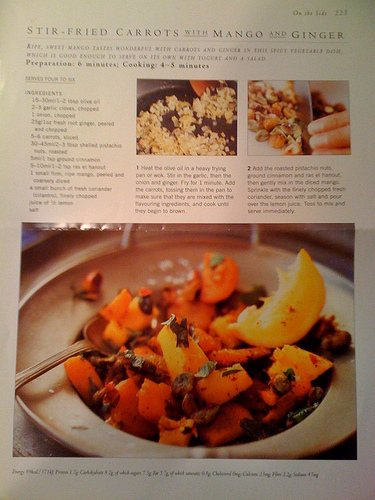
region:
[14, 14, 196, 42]
This is a stir-fried carrots recipie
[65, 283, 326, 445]
This is a picture of food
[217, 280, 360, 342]
This is a lemon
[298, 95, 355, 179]
This is a hand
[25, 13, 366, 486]
This is a recipe page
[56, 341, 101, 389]
This is a spoon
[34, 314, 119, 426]
The spoon is silver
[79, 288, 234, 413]
The carrots are orange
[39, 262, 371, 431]
This is a bowl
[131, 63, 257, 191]
This is a picture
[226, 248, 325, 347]
a lemon wedge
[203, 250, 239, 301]
slice of tomato with herb flakes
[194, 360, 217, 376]
an undetermined herb flake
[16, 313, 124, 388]
partial silver spoon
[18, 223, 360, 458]
silver serving platter with sauteed food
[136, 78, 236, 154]
thumbnail image of sauteed onions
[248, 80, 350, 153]
thumbnail image of chopping instructions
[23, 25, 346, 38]
recipe title for article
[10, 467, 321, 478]
a caption describing the recipe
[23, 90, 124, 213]
list of ingredients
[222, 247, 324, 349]
peice of food on a plate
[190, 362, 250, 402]
peice of food on a plate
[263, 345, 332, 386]
peice of food on a plate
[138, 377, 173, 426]
peice of food on a plate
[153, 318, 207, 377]
peice of food on a plate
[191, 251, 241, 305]
peice of food on a plate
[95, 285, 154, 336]
peice of food on a plate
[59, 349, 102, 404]
peice of food on a plate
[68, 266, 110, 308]
peice of food on a plate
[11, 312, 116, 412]
silver spoon on a plate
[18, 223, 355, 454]
a plate of food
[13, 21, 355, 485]
A recipe on a page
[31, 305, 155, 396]
a spoon in a bowl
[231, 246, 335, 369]
a lemon slice on a plate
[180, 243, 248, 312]
tomato slices on a plate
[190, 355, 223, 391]
green sage on food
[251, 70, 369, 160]
a hand chopping food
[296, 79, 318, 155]
a knife blade in a recipe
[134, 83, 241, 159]
a ground bread crumbs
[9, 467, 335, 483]
writing on bottom of page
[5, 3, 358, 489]
text and photographs of recipe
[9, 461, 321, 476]
tiny writing with nutritional information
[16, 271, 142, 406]
utensil on side of round plate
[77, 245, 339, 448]
lemon wedge resting on top of food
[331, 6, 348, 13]
page number in upper right-hand corner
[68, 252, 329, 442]
cut ingredients mixed together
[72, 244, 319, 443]
seasonings sprinkled over top of dish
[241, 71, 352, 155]
fingers over knife chopping food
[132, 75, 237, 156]
cooking utensil pushing ingredient in pan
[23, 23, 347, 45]
name of dish capitalized and underlined